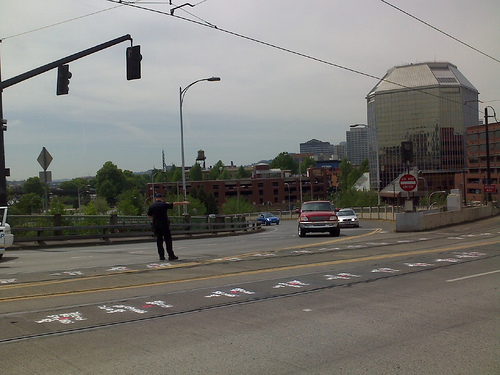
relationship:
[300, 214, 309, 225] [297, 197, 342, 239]
headlight of truck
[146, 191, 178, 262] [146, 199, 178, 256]
man in black outfit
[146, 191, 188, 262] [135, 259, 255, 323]
man on street